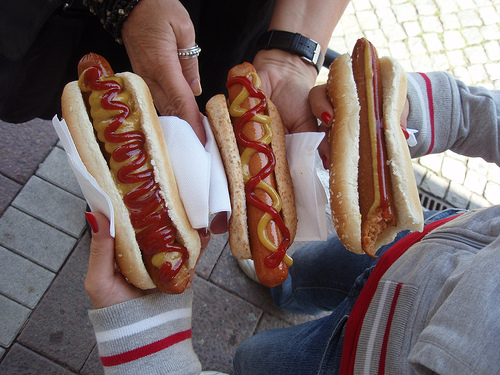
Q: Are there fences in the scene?
A: No, there are no fences.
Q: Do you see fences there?
A: No, there are no fences.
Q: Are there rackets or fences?
A: No, there are no fences or rackets.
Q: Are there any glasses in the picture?
A: No, there are no glasses.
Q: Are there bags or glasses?
A: No, there are no glasses or bags.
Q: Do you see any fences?
A: No, there are no fences.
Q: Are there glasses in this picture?
A: No, there are no glasses.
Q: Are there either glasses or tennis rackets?
A: No, there are no glasses or tennis rackets.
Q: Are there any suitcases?
A: No, there are no suitcases.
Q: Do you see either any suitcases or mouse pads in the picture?
A: No, there are no suitcases or mouse pads.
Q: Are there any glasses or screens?
A: No, there are no glasses or screens.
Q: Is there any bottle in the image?
A: No, there are no bottles.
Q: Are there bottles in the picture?
A: No, there are no bottles.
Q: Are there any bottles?
A: No, there are no bottles.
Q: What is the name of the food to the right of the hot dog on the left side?
A: The food is a bun.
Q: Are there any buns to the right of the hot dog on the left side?
A: Yes, there is a bun to the right of the hot dog.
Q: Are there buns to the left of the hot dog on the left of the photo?
A: No, the bun is to the right of the hot dog.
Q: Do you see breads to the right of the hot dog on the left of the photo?
A: No, there is a bun to the right of the hot dog.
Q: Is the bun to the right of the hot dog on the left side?
A: Yes, the bun is to the right of the hot dog.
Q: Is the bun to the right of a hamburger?
A: No, the bun is to the right of the hot dog.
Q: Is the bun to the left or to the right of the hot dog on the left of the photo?
A: The bun is to the right of the hot dog.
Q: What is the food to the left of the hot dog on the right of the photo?
A: The food is a bun.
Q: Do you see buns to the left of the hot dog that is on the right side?
A: Yes, there is a bun to the left of the hot dog.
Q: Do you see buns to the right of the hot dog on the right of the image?
A: No, the bun is to the left of the hot dog.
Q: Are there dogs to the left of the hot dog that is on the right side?
A: No, there is a bun to the left of the hot dog.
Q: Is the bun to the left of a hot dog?
A: Yes, the bun is to the left of a hot dog.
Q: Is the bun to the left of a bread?
A: No, the bun is to the left of a hot dog.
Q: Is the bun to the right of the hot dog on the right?
A: No, the bun is to the left of the hot dog.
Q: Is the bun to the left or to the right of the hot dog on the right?
A: The bun is to the left of the hot dog.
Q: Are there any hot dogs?
A: Yes, there is a hot dog.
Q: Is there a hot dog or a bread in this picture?
A: Yes, there is a hot dog.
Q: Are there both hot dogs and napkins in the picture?
A: Yes, there are both a hot dog and a napkin.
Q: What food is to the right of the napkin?
A: The food is a hot dog.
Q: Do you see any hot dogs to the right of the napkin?
A: Yes, there is a hot dog to the right of the napkin.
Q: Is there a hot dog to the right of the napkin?
A: Yes, there is a hot dog to the right of the napkin.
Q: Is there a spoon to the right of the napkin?
A: No, there is a hot dog to the right of the napkin.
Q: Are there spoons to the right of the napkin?
A: No, there is a hot dog to the right of the napkin.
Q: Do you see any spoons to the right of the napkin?
A: No, there is a hot dog to the right of the napkin.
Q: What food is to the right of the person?
A: The food is a hot dog.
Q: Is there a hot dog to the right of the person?
A: Yes, there is a hot dog to the right of the person.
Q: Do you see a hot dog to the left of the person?
A: No, the hot dog is to the right of the person.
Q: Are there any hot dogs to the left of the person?
A: No, the hot dog is to the right of the person.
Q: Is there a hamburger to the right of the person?
A: No, there is a hot dog to the right of the person.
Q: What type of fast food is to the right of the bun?
A: The food is a hot dog.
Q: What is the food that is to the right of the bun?
A: The food is a hot dog.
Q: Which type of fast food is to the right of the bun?
A: The food is a hot dog.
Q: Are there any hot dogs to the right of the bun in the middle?
A: Yes, there is a hot dog to the right of the bun.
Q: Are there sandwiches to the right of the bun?
A: No, there is a hot dog to the right of the bun.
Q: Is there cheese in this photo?
A: No, there is no cheese.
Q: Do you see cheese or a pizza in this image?
A: No, there are no cheese or pizzas.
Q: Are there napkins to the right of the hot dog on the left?
A: Yes, there is a napkin to the right of the hot dog.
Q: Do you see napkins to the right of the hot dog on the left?
A: Yes, there is a napkin to the right of the hot dog.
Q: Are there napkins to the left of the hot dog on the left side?
A: No, the napkin is to the right of the hot dog.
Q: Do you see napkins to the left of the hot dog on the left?
A: No, the napkin is to the right of the hot dog.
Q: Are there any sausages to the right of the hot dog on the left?
A: No, there is a napkin to the right of the hot dog.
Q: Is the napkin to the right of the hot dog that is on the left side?
A: Yes, the napkin is to the right of the hot dog.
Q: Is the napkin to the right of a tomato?
A: No, the napkin is to the right of the hot dog.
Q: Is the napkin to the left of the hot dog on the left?
A: No, the napkin is to the right of the hot dog.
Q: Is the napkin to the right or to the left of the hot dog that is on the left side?
A: The napkin is to the right of the hot dog.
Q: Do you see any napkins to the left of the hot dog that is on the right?
A: Yes, there is a napkin to the left of the hot dog.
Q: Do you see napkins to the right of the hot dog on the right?
A: No, the napkin is to the left of the hot dog.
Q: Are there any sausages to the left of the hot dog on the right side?
A: No, there is a napkin to the left of the hot dog.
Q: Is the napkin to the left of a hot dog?
A: Yes, the napkin is to the left of a hot dog.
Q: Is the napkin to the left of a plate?
A: No, the napkin is to the left of a hot dog.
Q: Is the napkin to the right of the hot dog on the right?
A: No, the napkin is to the left of the hot dog.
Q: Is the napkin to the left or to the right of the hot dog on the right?
A: The napkin is to the left of the hot dog.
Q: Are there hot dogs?
A: Yes, there is a hot dog.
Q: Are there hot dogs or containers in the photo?
A: Yes, there is a hot dog.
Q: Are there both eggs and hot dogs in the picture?
A: No, there is a hot dog but no eggs.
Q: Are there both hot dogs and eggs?
A: No, there is a hot dog but no eggs.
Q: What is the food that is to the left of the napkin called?
A: The food is a hot dog.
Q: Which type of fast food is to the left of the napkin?
A: The food is a hot dog.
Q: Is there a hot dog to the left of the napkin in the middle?
A: Yes, there is a hot dog to the left of the napkin.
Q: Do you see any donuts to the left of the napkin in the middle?
A: No, there is a hot dog to the left of the napkin.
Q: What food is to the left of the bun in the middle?
A: The food is a hot dog.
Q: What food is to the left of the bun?
A: The food is a hot dog.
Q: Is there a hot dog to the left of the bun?
A: Yes, there is a hot dog to the left of the bun.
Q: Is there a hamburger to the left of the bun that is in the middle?
A: No, there is a hot dog to the left of the bun.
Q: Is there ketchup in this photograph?
A: Yes, there is ketchup.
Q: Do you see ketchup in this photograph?
A: Yes, there is ketchup.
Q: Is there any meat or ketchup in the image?
A: Yes, there is ketchup.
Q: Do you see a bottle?
A: No, there are no bottles.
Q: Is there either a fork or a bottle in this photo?
A: No, there are no bottles or forks.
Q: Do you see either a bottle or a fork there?
A: No, there are no bottles or forks.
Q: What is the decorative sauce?
A: The sauce is ketchup.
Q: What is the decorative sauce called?
A: The sauce is ketchup.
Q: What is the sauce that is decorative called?
A: The sauce is ketchup.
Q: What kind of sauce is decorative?
A: The sauce is ketchup.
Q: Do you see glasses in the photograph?
A: No, there are no glasses.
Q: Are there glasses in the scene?
A: No, there are no glasses.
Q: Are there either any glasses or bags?
A: No, there are no glasses or bags.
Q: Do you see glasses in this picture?
A: No, there are no glasses.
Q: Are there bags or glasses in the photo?
A: No, there are no glasses or bags.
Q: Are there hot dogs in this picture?
A: Yes, there is a hot dog.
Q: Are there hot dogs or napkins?
A: Yes, there is a hot dog.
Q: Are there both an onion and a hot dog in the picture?
A: No, there is a hot dog but no onions.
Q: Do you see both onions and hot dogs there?
A: No, there is a hot dog but no onions.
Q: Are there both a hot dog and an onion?
A: No, there is a hot dog but no onions.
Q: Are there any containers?
A: No, there are no containers.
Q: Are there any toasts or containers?
A: No, there are no containers or toasts.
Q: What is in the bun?
A: The hot dog is in the bun.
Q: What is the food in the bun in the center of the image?
A: The food is a hot dog.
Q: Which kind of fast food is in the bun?
A: The food is a hot dog.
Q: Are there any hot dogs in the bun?
A: Yes, there is a hot dog in the bun.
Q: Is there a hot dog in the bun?
A: Yes, there is a hot dog in the bun.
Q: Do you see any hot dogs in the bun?
A: Yes, there is a hot dog in the bun.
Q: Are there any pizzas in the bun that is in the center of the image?
A: No, there is a hot dog in the bun.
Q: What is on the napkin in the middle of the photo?
A: The hot dog is on the napkin.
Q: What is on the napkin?
A: The hot dog is on the napkin.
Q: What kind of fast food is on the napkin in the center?
A: The food is a hot dog.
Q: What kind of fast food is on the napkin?
A: The food is a hot dog.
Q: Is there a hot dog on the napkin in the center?
A: Yes, there is a hot dog on the napkin.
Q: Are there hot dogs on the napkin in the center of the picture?
A: Yes, there is a hot dog on the napkin.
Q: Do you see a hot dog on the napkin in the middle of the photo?
A: Yes, there is a hot dog on the napkin.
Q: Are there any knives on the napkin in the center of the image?
A: No, there is a hot dog on the napkin.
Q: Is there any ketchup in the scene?
A: Yes, there is ketchup.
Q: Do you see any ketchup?
A: Yes, there is ketchup.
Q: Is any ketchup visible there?
A: Yes, there is ketchup.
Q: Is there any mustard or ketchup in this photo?
A: Yes, there is ketchup.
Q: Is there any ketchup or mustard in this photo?
A: Yes, there is ketchup.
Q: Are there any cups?
A: No, there are no cups.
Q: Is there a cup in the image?
A: No, there are no cups.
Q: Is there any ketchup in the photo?
A: Yes, there is ketchup.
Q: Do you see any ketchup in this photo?
A: Yes, there is ketchup.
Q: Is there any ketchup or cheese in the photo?
A: Yes, there is ketchup.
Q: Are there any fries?
A: No, there are no fries.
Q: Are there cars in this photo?
A: No, there are no cars.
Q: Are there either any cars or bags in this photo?
A: No, there are no cars or bags.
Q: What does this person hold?
A: The person holds the hot dog.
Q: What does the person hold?
A: The person holds the hot dog.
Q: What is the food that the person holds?
A: The food is a hot dog.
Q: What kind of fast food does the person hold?
A: The person holds the hot dog.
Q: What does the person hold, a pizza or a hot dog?
A: The person holds a hot dog.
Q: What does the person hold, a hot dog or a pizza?
A: The person holds a hot dog.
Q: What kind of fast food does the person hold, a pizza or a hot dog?
A: The person holds a hot dog.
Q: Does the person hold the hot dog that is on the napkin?
A: Yes, the person holds the hot dog.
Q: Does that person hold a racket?
A: No, the person holds the hot dog.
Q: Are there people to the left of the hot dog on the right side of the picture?
A: Yes, there is a person to the left of the hot dog.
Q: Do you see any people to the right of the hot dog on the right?
A: No, the person is to the left of the hot dog.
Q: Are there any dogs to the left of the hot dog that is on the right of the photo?
A: No, there is a person to the left of the hot dog.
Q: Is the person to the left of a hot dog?
A: Yes, the person is to the left of a hot dog.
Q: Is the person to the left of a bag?
A: No, the person is to the left of a hot dog.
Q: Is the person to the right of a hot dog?
A: No, the person is to the left of a hot dog.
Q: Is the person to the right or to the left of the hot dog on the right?
A: The person is to the left of the hot dog.